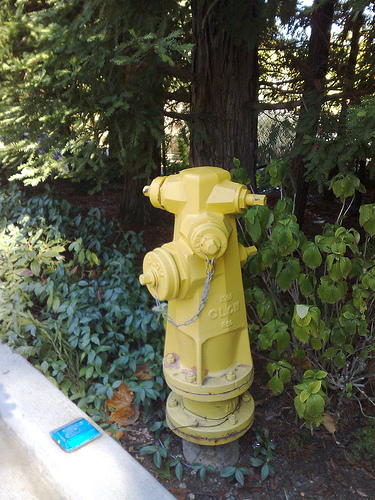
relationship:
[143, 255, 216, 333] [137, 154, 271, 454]
chain on hydrant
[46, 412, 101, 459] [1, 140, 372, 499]
reflector on ground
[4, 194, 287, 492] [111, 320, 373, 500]
leaves on dirt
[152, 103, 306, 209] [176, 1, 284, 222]
fence in trees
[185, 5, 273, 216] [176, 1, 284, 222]
trunk of trees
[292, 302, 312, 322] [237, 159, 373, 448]
leaf in bushes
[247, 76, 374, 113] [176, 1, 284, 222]
branches of trees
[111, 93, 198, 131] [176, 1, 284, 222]
branches of trees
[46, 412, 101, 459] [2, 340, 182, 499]
reflector on curb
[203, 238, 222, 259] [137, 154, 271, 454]
valve on hydrant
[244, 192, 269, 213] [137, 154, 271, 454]
valve on hydrant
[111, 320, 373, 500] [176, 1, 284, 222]
dirt under trees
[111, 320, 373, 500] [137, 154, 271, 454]
dirt to right of hydrant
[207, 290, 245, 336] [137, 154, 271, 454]
writing on hydrant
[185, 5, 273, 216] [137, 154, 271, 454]
trunk behind hydrant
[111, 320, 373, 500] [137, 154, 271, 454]
dirt next to hydrant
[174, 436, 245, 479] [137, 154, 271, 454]
base of hydrant